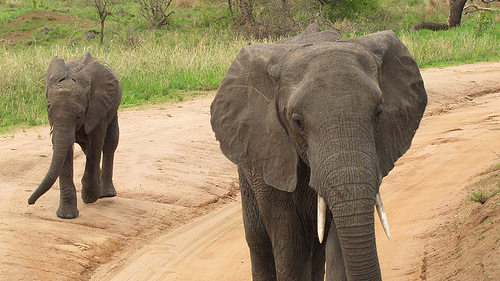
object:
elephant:
[209, 29, 426, 280]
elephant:
[24, 53, 123, 219]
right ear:
[209, 41, 312, 192]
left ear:
[355, 31, 427, 182]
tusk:
[316, 194, 326, 243]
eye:
[294, 117, 303, 128]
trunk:
[26, 118, 73, 205]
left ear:
[72, 52, 120, 135]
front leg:
[240, 160, 312, 281]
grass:
[122, 45, 212, 98]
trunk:
[304, 129, 383, 281]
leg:
[236, 168, 275, 281]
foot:
[56, 208, 79, 219]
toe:
[66, 213, 73, 219]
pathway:
[0, 59, 498, 281]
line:
[343, 119, 351, 181]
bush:
[227, 1, 301, 40]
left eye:
[376, 109, 384, 119]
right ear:
[45, 56, 68, 98]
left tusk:
[373, 193, 389, 239]